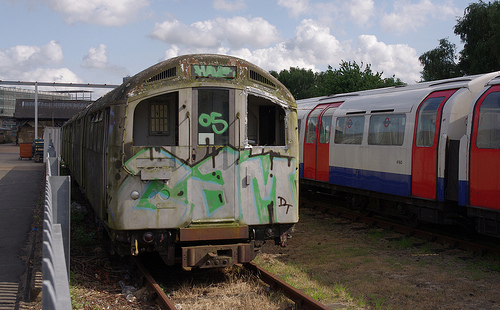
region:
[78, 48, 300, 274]
train on the track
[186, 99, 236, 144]
green front of the train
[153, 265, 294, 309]
track under the train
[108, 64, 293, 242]
paint on the front of the train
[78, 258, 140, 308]
shadow next to the train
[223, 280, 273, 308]
light hitting the track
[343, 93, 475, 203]
blue, white and red train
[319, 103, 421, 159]
windows on the side of the train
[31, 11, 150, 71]
clouds in the sky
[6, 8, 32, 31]
blue sky behind the clouds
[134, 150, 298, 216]
Graffiti on the train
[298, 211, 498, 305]
Grass beside the trains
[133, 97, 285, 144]
Busted windows on the train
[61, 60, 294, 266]
An old train on the tracks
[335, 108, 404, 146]
Windows on the newer train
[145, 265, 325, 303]
Old tracks beneath the train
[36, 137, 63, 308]
A fence by the train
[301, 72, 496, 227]
A newer train on the tracks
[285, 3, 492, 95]
Trees behind the trains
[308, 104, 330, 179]
A door on the newer train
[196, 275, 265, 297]
grass growing in the middle of track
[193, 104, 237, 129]
green lettering on train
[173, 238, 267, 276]
rusted metal on front of train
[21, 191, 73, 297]
blue barrier on platform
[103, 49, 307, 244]
rusted front of discarded train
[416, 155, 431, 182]
red paint on train door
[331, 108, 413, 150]
large window on side of train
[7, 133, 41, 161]
orange container on ground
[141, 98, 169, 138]
window in train front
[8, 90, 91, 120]
black cover on building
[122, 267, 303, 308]
track in the railway station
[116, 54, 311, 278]
front part of the train engine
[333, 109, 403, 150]
window of the train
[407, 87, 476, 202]
red color door in the train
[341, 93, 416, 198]
white color with two windows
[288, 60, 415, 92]
tree behind the train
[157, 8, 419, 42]
sky blue with white clouds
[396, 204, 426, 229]
wheel of the train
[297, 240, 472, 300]
dirt with grass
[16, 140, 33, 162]
dustpin in the platform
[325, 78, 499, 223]
the train is new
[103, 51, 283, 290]
the tree is old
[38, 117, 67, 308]
the railing is grey in colour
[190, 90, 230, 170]
the train has some writtings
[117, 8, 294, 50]
the sky is cloudy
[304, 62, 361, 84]
a tree is growing next to the train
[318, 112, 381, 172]
the train is brightly coloured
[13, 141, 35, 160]
the bin is red in colour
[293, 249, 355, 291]
grass growing between the railway lines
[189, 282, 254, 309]
brown grass on the railwatracks